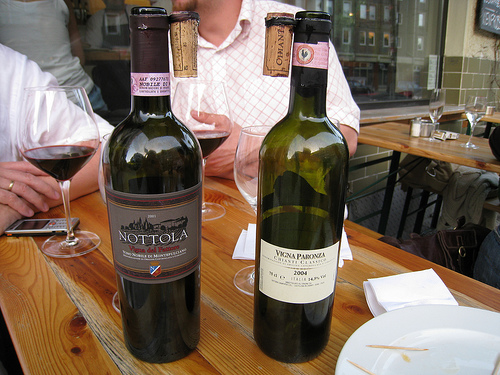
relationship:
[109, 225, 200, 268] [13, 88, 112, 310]
writing on glass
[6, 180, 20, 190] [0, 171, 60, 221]
ring on finger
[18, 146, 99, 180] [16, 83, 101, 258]
red wine inside clear glass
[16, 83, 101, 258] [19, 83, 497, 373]
clear glass on table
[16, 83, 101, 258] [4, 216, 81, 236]
clear glass next to cell phone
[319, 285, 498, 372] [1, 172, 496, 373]
plate on table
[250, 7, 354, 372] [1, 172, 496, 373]
bottle on table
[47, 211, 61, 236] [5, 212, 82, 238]
button on cellphone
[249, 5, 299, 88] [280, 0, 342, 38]
cork attached to top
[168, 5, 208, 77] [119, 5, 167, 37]
cork attached to top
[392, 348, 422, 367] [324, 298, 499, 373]
crumbs on plate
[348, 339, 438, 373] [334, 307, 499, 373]
toothpicks on plate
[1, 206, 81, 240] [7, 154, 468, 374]
cell phone on table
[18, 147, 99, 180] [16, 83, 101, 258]
red wine in clear glass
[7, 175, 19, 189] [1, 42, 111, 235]
ring on finger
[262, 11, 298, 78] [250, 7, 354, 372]
cork in bottle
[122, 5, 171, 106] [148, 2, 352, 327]
foil on bottle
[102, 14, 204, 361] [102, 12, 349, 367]
wine in bottles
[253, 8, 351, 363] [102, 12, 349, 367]
champagne in bottles